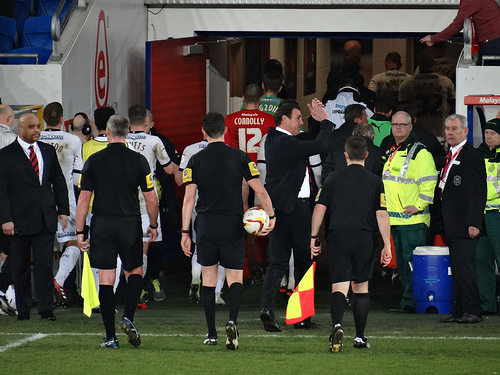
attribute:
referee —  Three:
[183, 133, 284, 336]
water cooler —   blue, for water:
[417, 211, 497, 320]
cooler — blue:
[409, 237, 457, 325]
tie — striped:
[10, 134, 51, 177]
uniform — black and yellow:
[314, 159, 390, 289]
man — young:
[308, 133, 395, 351]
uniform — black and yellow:
[315, 164, 389, 283]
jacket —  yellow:
[380, 141, 437, 230]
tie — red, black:
[28, 145, 38, 175]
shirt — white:
[36, 129, 82, 206]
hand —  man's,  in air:
[307, 91, 323, 118]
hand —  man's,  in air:
[311, 99, 328, 129]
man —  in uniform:
[306, 123, 415, 373]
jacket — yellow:
[391, 132, 449, 207]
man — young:
[181, 108, 276, 349]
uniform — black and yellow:
[181, 138, 262, 348]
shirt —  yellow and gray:
[375, 142, 439, 227]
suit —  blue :
[0, 138, 71, 315]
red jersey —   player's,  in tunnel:
[219, 79, 279, 156]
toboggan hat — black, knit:
[475, 109, 498, 136]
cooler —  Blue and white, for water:
[398, 225, 459, 324]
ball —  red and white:
[238, 205, 268, 237]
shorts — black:
[192, 213, 251, 275]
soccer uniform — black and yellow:
[184, 147, 244, 271]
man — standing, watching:
[432, 105, 489, 326]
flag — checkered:
[287, 237, 322, 324]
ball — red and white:
[239, 199, 276, 240]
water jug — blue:
[408, 246, 453, 313]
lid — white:
[412, 243, 449, 255]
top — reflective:
[377, 156, 444, 213]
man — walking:
[261, 94, 320, 340]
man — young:
[75, 113, 157, 347]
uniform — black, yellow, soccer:
[78, 141, 154, 271]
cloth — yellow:
[64, 237, 96, 321]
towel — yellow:
[74, 242, 107, 322]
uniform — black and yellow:
[66, 138, 166, 350]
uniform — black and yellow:
[175, 137, 267, 352]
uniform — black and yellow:
[305, 153, 393, 355]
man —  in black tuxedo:
[0, 106, 80, 326]